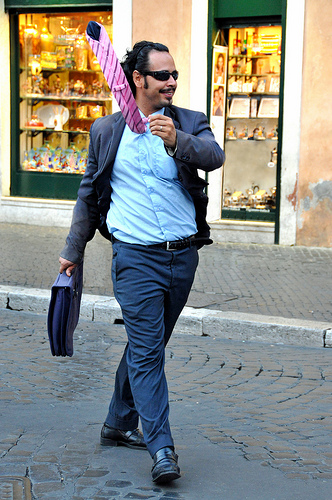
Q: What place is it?
A: It is a street.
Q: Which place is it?
A: It is a street.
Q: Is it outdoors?
A: Yes, it is outdoors.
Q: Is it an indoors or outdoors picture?
A: It is outdoors.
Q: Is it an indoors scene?
A: No, it is outdoors.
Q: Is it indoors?
A: No, it is outdoors.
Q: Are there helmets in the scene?
A: No, there are no helmets.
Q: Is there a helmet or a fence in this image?
A: No, there are no helmets or fences.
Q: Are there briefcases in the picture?
A: Yes, there is a briefcase.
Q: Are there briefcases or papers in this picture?
A: Yes, there is a briefcase.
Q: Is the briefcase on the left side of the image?
A: Yes, the briefcase is on the left of the image.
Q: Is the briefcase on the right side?
A: No, the briefcase is on the left of the image.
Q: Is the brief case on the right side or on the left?
A: The brief case is on the left of the image.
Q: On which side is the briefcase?
A: The briefcase is on the left of the image.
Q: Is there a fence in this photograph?
A: No, there are no fences.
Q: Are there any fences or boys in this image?
A: No, there are no fences or boys.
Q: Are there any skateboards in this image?
A: No, there are no skateboards.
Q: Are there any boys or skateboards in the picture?
A: No, there are no skateboards or boys.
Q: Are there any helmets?
A: No, there are no helmets.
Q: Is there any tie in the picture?
A: Yes, there is a tie.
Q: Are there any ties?
A: Yes, there is a tie.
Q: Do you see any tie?
A: Yes, there is a tie.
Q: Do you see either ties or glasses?
A: Yes, there is a tie.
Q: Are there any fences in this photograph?
A: No, there are no fences.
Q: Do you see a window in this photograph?
A: Yes, there is a window.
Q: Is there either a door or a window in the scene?
A: Yes, there is a window.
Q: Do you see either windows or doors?
A: Yes, there is a window.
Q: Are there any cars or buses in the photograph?
A: No, there are no cars or buses.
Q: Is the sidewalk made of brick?
A: Yes, the sidewalk is made of brick.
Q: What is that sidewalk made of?
A: The sidewalk is made of brick.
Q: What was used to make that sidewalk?
A: The sidewalk is made of brick.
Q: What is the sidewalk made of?
A: The sidewalk is made of brick.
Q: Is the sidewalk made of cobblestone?
A: No, the sidewalk is made of brick.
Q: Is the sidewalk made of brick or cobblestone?
A: The sidewalk is made of brick.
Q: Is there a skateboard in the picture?
A: No, there are no skateboards.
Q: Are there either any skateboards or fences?
A: No, there are no skateboards or fences.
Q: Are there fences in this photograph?
A: No, there are no fences.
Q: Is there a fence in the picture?
A: No, there are no fences.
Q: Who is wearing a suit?
A: The man is wearing a suit.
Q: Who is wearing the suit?
A: The man is wearing a suit.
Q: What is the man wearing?
A: The man is wearing a suit.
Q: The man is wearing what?
A: The man is wearing a suit.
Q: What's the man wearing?
A: The man is wearing a suit.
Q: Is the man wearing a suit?
A: Yes, the man is wearing a suit.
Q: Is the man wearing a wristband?
A: No, the man is wearing a suit.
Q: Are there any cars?
A: No, there are no cars.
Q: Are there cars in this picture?
A: No, there are no cars.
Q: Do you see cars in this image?
A: No, there are no cars.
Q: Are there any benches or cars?
A: No, there are no cars or benches.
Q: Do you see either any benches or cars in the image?
A: No, there are no cars or benches.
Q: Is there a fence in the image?
A: No, there are no fences.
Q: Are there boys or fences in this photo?
A: No, there are no fences or boys.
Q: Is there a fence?
A: No, there are no fences.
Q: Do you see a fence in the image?
A: No, there are no fences.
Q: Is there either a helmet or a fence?
A: No, there are no helmets or fences.